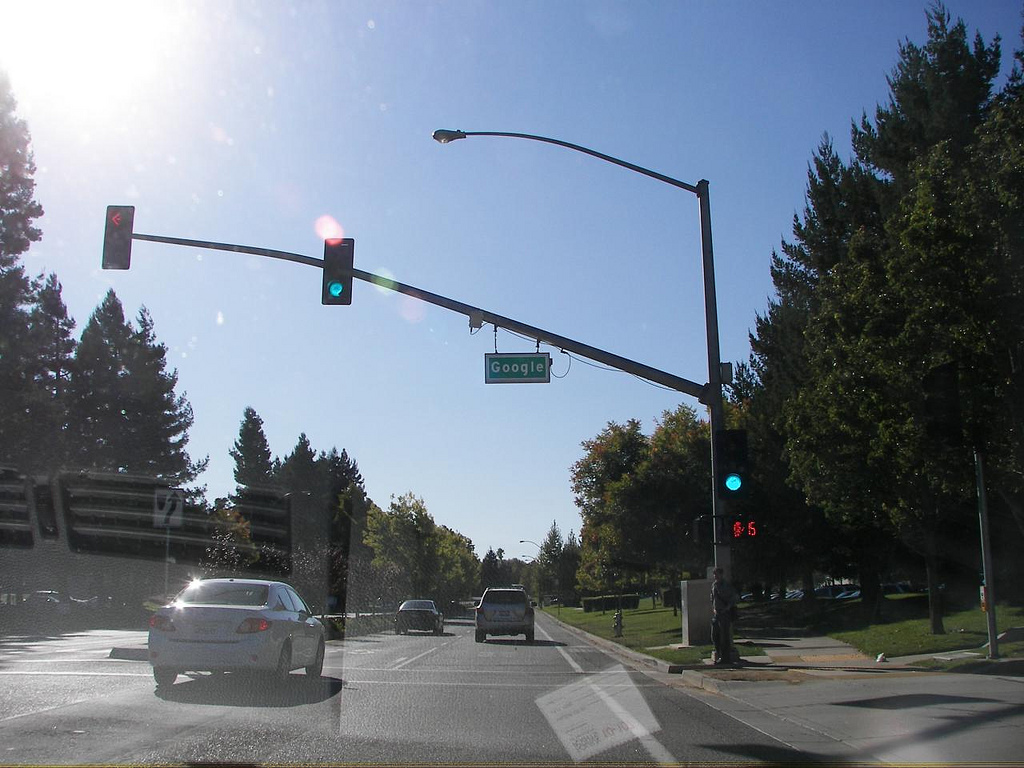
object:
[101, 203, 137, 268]
signal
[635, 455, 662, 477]
leaves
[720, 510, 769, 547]
signal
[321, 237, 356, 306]
signal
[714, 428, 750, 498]
signal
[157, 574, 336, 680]
car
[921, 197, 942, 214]
leaves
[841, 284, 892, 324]
green leaves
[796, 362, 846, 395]
green leaves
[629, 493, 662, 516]
green leaves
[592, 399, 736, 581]
tree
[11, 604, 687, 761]
street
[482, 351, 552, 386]
sign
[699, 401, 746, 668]
pole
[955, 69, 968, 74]
leaf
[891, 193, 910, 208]
leaf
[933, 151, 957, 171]
leaf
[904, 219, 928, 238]
leaf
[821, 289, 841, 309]
leaf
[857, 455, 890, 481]
leaves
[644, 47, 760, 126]
blue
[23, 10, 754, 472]
sky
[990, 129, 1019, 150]
leaves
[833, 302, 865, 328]
leaves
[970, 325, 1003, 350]
leaves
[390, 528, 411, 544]
leaves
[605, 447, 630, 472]
leaves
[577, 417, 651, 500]
tree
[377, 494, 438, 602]
tree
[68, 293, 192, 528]
tree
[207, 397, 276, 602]
tree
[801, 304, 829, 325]
leaves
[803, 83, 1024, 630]
tree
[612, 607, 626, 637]
hydrant grass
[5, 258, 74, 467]
trees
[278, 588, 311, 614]
windows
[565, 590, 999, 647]
grass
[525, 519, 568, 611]
tree